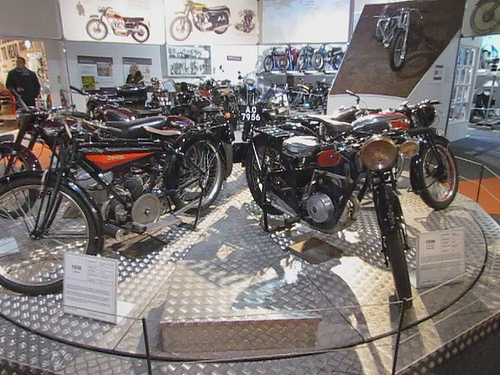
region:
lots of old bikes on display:
[2, 51, 494, 369]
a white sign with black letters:
[53, 247, 141, 347]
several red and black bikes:
[21, 74, 457, 319]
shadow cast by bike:
[170, 166, 371, 371]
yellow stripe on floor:
[448, 166, 498, 221]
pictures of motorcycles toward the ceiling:
[64, 5, 278, 50]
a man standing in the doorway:
[0, 38, 68, 161]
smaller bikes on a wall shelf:
[260, 42, 352, 77]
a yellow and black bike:
[177, 3, 251, 40]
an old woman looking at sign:
[110, 52, 153, 103]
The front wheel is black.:
[375, 188, 412, 305]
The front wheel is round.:
[376, 187, 416, 309]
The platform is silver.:
[161, 255, 333, 330]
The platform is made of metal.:
[153, 253, 325, 343]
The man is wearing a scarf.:
[6, 58, 41, 110]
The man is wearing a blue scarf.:
[3, 53, 43, 108]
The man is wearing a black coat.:
[6, 56, 42, 105]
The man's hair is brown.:
[4, 55, 45, 107]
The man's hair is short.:
[3, 53, 43, 109]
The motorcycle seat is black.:
[303, 109, 354, 134]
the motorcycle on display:
[228, 103, 435, 303]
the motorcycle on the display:
[12, 90, 230, 247]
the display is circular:
[8, 178, 498, 372]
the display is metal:
[6, 202, 498, 374]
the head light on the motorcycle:
[340, 128, 401, 180]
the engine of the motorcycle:
[294, 181, 346, 235]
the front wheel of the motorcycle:
[375, 186, 425, 303]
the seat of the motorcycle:
[281, 130, 312, 165]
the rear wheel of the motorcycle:
[167, 135, 227, 216]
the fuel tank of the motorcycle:
[68, 141, 159, 172]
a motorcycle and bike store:
[1, 2, 498, 372]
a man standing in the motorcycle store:
[4, 57, 40, 108]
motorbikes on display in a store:
[0, 83, 498, 373]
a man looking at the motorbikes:
[5, 57, 41, 107]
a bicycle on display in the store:
[365, 1, 425, 71]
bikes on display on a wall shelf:
[260, 41, 338, 74]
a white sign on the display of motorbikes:
[60, 248, 135, 325]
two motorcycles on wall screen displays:
[62, 0, 258, 43]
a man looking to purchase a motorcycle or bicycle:
[4, 55, 42, 109]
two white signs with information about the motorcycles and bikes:
[60, 228, 466, 325]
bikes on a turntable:
[13, 74, 479, 342]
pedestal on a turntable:
[161, 241, 321, 351]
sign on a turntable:
[51, 248, 136, 338]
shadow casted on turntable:
[201, 220, 284, 297]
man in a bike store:
[4, 48, 62, 127]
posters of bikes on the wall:
[66, 1, 271, 53]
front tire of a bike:
[4, 160, 109, 310]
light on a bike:
[363, 133, 398, 178]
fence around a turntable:
[464, 153, 495, 218]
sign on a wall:
[71, 49, 118, 94]